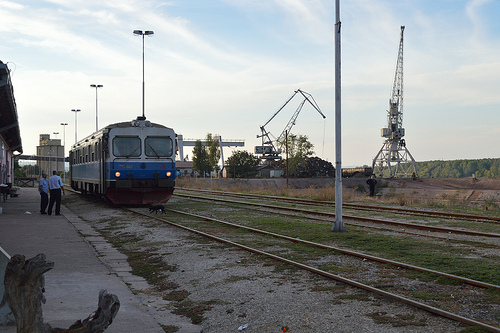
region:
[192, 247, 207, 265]
black mark is spotted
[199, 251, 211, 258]
black mark is spotted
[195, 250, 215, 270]
black mark is spotted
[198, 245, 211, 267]
black mark is spotted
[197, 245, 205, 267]
black mark is spotted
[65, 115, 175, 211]
a blue and white commuter train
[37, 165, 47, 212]
a person standing on sidewalk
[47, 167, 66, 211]
a person standing on sidewalk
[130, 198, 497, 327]
a set of railroad tracks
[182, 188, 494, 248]
a set of railroad tracks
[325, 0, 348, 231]
a tall metal pole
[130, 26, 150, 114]
a tall overhead light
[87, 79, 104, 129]
a tall overhead light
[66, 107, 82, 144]
a tall overhead light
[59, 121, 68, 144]
a tall overhead light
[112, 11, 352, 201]
the sky is clear and visible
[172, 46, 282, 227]
the sky is clear and visible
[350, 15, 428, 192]
a large crane in the sky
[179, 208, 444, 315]
metal train tracks on the ground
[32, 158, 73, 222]
two men standing by the train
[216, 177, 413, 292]
tracks covered with moss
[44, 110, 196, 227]
a train stopped on the tracks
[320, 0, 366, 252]
a metal light pole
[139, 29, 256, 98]
white clouds in the blue sky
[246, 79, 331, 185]
large bent crane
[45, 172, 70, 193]
a blue shirt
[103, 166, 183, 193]
headlights of the train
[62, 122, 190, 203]
train is o the tracks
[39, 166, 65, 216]
men standing near the train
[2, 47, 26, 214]
train station building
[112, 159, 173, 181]
train lights are on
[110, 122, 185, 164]
two windows at front of train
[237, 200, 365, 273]
grass growing between tracks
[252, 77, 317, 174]
construction equipment being used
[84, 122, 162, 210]
train is blue and white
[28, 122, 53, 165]
building is in the distance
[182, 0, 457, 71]
sky is filled with light wispy clouds